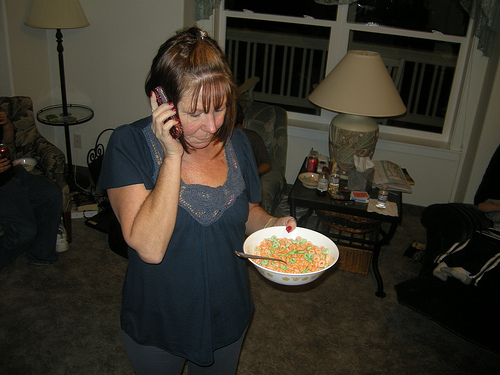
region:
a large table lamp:
[304, 44, 407, 181]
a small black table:
[281, 158, 408, 308]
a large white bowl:
[244, 227, 340, 287]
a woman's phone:
[153, 86, 182, 136]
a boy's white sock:
[440, 264, 475, 282]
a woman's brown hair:
[147, 23, 240, 160]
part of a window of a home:
[340, 13, 467, 144]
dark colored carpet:
[3, 215, 468, 373]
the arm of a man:
[245, 128, 271, 173]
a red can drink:
[303, 152, 317, 174]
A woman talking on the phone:
[100, 16, 340, 371]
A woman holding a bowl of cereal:
[95, 15, 340, 370]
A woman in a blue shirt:
[90, 21, 325, 371]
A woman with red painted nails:
[90, 10, 337, 370]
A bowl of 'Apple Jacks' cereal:
[232, 220, 338, 285]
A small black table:
[281, 142, 401, 297]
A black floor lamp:
[22, 0, 97, 197]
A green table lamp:
[305, 32, 410, 174]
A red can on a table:
[300, 150, 320, 175]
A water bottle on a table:
[325, 165, 342, 196]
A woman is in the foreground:
[81, 19, 345, 374]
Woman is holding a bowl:
[213, 208, 355, 303]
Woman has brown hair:
[143, 18, 246, 173]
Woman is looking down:
[136, 15, 259, 171]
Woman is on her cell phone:
[128, 26, 253, 158]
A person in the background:
[1, 105, 72, 280]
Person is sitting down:
[1, 93, 77, 282]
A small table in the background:
[275, 148, 414, 311]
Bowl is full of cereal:
[232, 215, 347, 293]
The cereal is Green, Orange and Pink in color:
[228, 208, 347, 297]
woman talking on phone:
[96, 25, 296, 370]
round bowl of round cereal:
[242, 225, 339, 287]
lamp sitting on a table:
[307, 47, 409, 185]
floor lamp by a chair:
[26, 0, 96, 204]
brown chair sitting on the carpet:
[393, 141, 498, 353]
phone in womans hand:
[148, 85, 185, 142]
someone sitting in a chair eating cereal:
[0, 93, 72, 270]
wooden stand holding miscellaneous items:
[284, 148, 409, 298]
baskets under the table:
[318, 207, 378, 277]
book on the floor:
[72, 186, 99, 213]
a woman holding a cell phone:
[148, 85, 182, 152]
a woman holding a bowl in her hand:
[241, 225, 339, 285]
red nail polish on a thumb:
[286, 224, 293, 233]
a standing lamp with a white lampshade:
[22, 0, 97, 201]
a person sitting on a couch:
[0, 105, 63, 272]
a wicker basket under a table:
[323, 224, 377, 275]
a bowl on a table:
[299, 170, 324, 186]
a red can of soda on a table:
[306, 155, 319, 170]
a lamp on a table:
[306, 46, 406, 178]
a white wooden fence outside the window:
[227, 23, 456, 123]